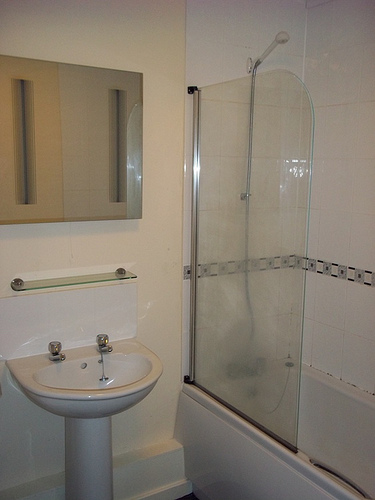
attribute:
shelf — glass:
[8, 265, 138, 292]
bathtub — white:
[191, 399, 372, 484]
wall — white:
[1, 15, 185, 493]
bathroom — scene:
[12, 69, 372, 498]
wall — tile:
[0, 12, 182, 335]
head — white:
[261, 22, 295, 52]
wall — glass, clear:
[183, 69, 314, 453]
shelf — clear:
[10, 260, 135, 292]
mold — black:
[301, 359, 373, 396]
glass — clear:
[183, 67, 326, 452]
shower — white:
[171, 11, 371, 498]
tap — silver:
[47, 340, 66, 363]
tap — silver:
[94, 332, 113, 353]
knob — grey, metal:
[49, 340, 61, 353]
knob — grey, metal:
[96, 334, 107, 346]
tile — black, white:
[183, 265, 196, 280]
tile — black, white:
[206, 260, 219, 277]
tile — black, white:
[239, 259, 250, 272]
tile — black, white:
[265, 256, 275, 268]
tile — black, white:
[320, 257, 333, 276]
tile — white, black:
[258, 256, 266, 270]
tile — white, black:
[281, 254, 289, 268]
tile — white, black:
[305, 257, 316, 272]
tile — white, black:
[329, 263, 338, 277]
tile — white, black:
[345, 263, 357, 282]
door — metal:
[1, 53, 68, 226]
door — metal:
[55, 59, 143, 222]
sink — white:
[5, 335, 164, 420]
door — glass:
[188, 67, 312, 454]